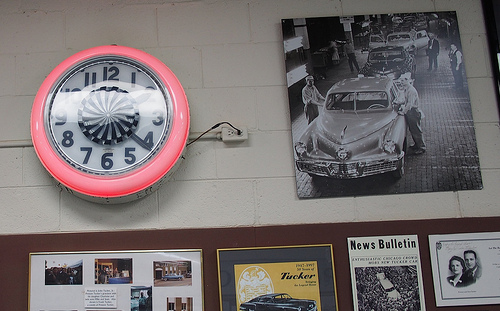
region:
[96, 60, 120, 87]
The number is black.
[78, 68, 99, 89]
The number is black.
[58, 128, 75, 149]
The number is black.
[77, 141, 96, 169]
The number is black.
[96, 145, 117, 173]
The number is black.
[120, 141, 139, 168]
The number is black.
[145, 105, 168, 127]
The number is black.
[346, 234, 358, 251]
The letter is black.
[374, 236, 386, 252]
The letter is black.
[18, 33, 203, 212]
The clock is round.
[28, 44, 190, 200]
round clock hanging on wall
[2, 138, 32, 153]
conduit behind clock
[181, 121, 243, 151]
black cord next to clock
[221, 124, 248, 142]
outlet attached to conduit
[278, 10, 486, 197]
poster is hanging on the wall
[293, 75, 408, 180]
car printed on poster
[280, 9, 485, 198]
poster to the right of outlet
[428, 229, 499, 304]
certificate hanging below poster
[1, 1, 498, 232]
wall behind clock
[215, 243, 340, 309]
framed picture is hanging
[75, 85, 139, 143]
the center of the clock is black and white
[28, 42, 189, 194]
the neon is pink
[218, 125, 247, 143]
the outlet is white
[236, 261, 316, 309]
the poster is yellow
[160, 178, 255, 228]
the cinder block is white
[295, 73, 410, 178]
the car is old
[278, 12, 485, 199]
the poster is black and white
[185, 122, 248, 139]
the clock is plugged in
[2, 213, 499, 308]
the wall is brown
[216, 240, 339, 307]
the frame is gold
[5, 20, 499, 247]
clock and photo on wall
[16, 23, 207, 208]
clock has white background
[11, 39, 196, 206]
clock has pink trim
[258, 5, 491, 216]
photograph is black and white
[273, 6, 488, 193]
photograph has cars on it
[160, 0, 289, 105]
wall is tan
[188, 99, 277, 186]
wall socket next to clock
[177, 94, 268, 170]
plug plugged into clock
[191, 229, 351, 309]
blue and yellow photo on wall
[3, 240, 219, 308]
framed photographs on wall